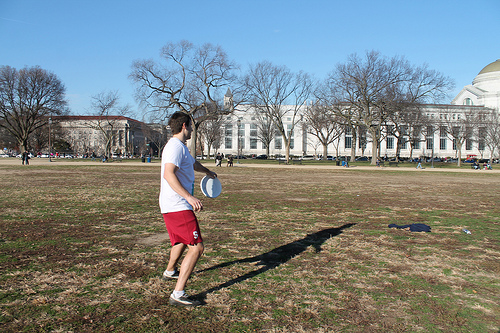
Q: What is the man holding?
A: A frisbee.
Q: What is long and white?
A: A building.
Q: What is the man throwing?
A: A frisbee.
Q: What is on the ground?
A: The man's shadow.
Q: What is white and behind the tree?
A: The building.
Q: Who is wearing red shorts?
A: The man.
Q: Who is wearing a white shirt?
A: The man.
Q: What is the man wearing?
A: Sneakers.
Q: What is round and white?
A: The building.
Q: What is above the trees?
A: The sky.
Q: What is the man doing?
A: Tossing a frisbee.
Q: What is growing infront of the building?
A: Trees.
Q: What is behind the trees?
A: A building.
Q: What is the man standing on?
A: Grass.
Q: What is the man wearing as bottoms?
A: Shorts.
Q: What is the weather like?
A: Sunny.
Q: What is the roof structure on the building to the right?
A: A dome.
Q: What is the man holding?
A: A frisbee.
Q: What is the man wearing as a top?
A: A tshirt.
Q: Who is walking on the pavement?
A: A group of people.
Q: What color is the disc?
A: White.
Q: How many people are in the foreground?
A: One.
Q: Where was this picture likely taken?
A: University.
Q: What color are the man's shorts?
A: Red.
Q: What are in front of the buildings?
A: Trees.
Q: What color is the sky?
A: Blue.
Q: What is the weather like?
A: Clear.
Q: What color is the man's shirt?
A: White.